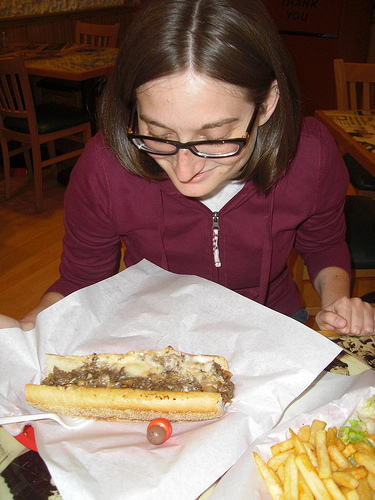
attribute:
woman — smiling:
[3, 5, 374, 337]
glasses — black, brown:
[121, 99, 261, 160]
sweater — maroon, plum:
[45, 115, 355, 316]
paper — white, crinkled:
[2, 259, 342, 499]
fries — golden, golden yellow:
[250, 422, 373, 499]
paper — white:
[201, 370, 374, 499]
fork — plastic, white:
[2, 411, 99, 433]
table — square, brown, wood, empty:
[3, 38, 118, 85]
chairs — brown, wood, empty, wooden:
[0, 20, 126, 202]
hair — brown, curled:
[99, 1, 304, 196]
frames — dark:
[127, 108, 259, 159]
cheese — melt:
[99, 345, 221, 388]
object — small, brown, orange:
[142, 417, 171, 445]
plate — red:
[4, 334, 245, 464]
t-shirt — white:
[195, 169, 246, 212]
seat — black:
[9, 79, 108, 135]